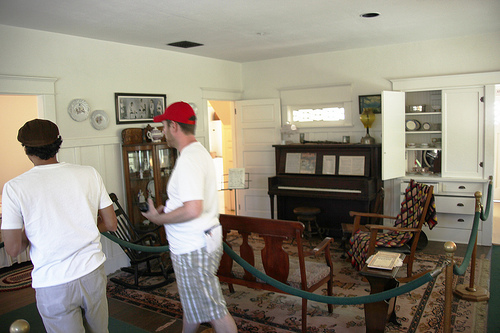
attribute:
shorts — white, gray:
[167, 267, 264, 317]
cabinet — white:
[445, 93, 479, 180]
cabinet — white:
[381, 86, 432, 174]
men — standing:
[3, 90, 323, 313]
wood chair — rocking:
[341, 154, 441, 276]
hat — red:
[152, 101, 194, 126]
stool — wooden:
[292, 200, 329, 243]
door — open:
[202, 94, 294, 216]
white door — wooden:
[235, 98, 285, 220]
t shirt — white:
[1, 160, 113, 290]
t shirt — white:
[161, 140, 223, 257]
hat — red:
[145, 95, 204, 130]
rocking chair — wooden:
[348, 177, 434, 283]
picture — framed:
[75, 84, 185, 128]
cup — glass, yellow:
[358, 109, 380, 148]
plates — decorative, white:
[65, 95, 120, 139]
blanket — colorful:
[365, 184, 420, 241]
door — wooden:
[234, 98, 283, 218]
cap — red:
[152, 99, 203, 125]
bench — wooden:
[216, 205, 339, 322]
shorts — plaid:
[165, 244, 225, 326]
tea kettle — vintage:
[146, 124, 165, 144]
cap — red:
[144, 97, 198, 129]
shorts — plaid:
[168, 239, 230, 322]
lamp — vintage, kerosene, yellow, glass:
[355, 108, 377, 148]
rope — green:
[220, 245, 449, 302]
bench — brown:
[217, 213, 336, 331]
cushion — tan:
[228, 249, 330, 290]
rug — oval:
[2, 260, 34, 294]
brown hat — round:
[15, 121, 65, 146]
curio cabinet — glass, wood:
[121, 124, 169, 242]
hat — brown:
[16, 117, 61, 148]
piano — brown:
[266, 138, 376, 225]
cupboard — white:
[315, 87, 499, 221]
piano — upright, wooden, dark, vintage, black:
[266, 137, 381, 240]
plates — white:
[63, 97, 112, 131]